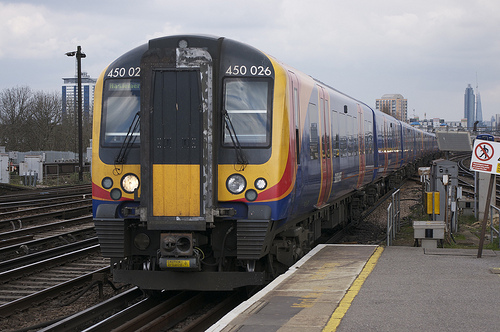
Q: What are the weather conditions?
A: It is cloudy.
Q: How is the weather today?
A: It is cloudy.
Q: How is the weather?
A: It is cloudy.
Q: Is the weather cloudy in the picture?
A: Yes, it is cloudy.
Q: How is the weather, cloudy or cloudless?
A: It is cloudy.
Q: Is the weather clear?
A: No, it is cloudy.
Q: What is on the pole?
A: The sign is on the pole.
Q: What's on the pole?
A: The sign is on the pole.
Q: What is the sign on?
A: The sign is on the pole.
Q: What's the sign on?
A: The sign is on the pole.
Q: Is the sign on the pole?
A: Yes, the sign is on the pole.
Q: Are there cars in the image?
A: No, there are no cars.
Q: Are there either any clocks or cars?
A: No, there are no cars or clocks.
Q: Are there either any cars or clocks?
A: No, there are no cars or clocks.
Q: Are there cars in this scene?
A: No, there are no cars.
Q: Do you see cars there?
A: No, there are no cars.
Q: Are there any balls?
A: No, there are no balls.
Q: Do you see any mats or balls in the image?
A: No, there are no balls or mats.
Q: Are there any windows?
A: Yes, there is a window.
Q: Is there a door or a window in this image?
A: Yes, there is a window.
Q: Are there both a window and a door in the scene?
A: Yes, there are both a window and a door.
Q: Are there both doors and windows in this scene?
A: Yes, there are both a window and a door.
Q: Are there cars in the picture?
A: No, there are no cars.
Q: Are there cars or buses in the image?
A: No, there are no cars or buses.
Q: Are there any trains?
A: Yes, there is a train.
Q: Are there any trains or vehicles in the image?
A: Yes, there is a train.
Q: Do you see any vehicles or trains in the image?
A: Yes, there is a train.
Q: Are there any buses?
A: No, there are no buses.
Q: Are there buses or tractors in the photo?
A: No, there are no buses or tractors.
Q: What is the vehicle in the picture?
A: The vehicle is a train.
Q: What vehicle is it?
A: The vehicle is a train.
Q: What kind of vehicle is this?
A: That is a train.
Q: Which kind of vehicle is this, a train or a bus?
A: That is a train.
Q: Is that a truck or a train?
A: That is a train.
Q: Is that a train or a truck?
A: That is a train.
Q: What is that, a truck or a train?
A: That is a train.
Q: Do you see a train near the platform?
A: Yes, there is a train near the platform.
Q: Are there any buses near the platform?
A: No, there is a train near the platform.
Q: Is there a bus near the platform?
A: No, there is a train near the platform.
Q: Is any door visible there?
A: Yes, there are doors.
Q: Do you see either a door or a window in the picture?
A: Yes, there are doors.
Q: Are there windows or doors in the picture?
A: Yes, there are doors.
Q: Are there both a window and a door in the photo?
A: Yes, there are both a door and a window.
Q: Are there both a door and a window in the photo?
A: Yes, there are both a door and a window.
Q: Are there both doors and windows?
A: Yes, there are both doors and a window.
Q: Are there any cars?
A: No, there are no cars.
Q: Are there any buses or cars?
A: No, there are no cars or buses.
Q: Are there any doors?
A: Yes, there are doors.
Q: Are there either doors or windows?
A: Yes, there are doors.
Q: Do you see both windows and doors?
A: Yes, there are both doors and a window.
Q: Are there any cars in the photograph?
A: No, there are no cars.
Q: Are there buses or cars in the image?
A: No, there are no cars or buses.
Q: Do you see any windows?
A: Yes, there is a window.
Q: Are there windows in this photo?
A: Yes, there is a window.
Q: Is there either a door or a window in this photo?
A: Yes, there is a window.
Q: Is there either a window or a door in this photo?
A: Yes, there is a window.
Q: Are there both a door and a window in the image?
A: Yes, there are both a window and a door.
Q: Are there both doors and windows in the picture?
A: Yes, there are both a window and a door.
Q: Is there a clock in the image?
A: No, there are no clocks.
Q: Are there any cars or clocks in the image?
A: No, there are no clocks or cars.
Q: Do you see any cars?
A: No, there are no cars.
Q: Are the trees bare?
A: Yes, the trees are bare.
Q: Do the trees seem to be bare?
A: Yes, the trees are bare.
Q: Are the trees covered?
A: No, the trees are bare.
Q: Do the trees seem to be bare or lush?
A: The trees are bare.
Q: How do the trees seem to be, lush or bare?
A: The trees are bare.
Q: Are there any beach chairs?
A: No, there are no beach chairs.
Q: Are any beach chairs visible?
A: No, there are no beach chairs.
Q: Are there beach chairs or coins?
A: No, there are no beach chairs or coins.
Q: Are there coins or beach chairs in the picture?
A: No, there are no beach chairs or coins.